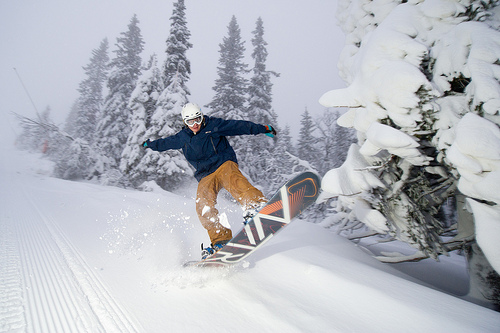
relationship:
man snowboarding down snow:
[139, 102, 276, 260] [0, 168, 500, 333]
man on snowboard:
[139, 102, 276, 260] [186, 164, 324, 277]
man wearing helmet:
[139, 102, 276, 260] [175, 99, 204, 122]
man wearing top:
[139, 102, 276, 260] [124, 114, 273, 174]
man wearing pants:
[137, 106, 313, 247] [191, 163, 264, 247]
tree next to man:
[309, 5, 496, 297] [139, 102, 276, 260]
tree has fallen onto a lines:
[10, 104, 99, 180] [1, 186, 76, 315]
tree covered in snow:
[6, 104, 104, 182] [69, 140, 75, 150]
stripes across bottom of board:
[233, 213, 282, 258] [181, 170, 321, 268]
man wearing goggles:
[139, 102, 276, 260] [185, 115, 204, 130]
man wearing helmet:
[139, 102, 276, 260] [175, 104, 201, 123]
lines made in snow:
[4, 170, 164, 330] [77, 279, 180, 330]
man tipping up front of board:
[139, 102, 276, 260] [178, 170, 318, 283]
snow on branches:
[317, 0, 500, 277] [341, 54, 478, 237]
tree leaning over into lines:
[6, 104, 104, 182] [1, 186, 76, 315]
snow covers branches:
[342, 55, 422, 151] [368, 55, 484, 271]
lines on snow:
[1, 186, 76, 315] [24, 172, 180, 332]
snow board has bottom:
[192, 166, 324, 278] [228, 195, 286, 260]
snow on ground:
[39, 223, 420, 317] [13, 174, 494, 332]